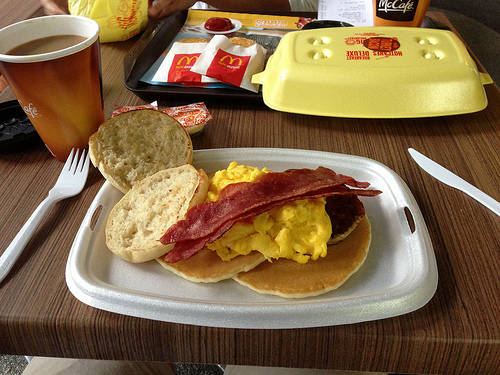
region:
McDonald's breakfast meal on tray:
[64, 108, 438, 327]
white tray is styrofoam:
[62, 148, 438, 329]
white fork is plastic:
[1, 148, 92, 279]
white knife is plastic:
[407, 146, 499, 217]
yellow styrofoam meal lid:
[250, 25, 494, 119]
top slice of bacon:
[157, 165, 371, 245]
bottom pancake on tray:
[230, 216, 371, 299]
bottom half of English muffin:
[103, 163, 210, 264]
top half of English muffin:
[87, 108, 194, 194]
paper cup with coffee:
[1, 14, 102, 162]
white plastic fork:
[2, 148, 90, 275]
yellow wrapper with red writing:
[66, 0, 147, 40]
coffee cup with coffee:
[1, 15, 107, 162]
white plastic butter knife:
[405, 145, 499, 216]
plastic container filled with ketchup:
[201, 15, 241, 36]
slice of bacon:
[159, 166, 371, 245]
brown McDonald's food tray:
[121, 8, 486, 108]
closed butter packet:
[161, 100, 216, 132]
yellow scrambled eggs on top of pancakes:
[201, 161, 326, 262]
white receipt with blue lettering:
[316, 0, 373, 28]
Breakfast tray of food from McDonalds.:
[61, 114, 438, 329]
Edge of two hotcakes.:
[191, 250, 358, 299]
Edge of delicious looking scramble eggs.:
[239, 210, 335, 266]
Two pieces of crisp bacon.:
[158, 167, 382, 225]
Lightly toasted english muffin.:
[88, 108, 201, 264]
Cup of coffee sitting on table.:
[5, 12, 105, 158]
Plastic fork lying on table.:
[1, 150, 98, 293]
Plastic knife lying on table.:
[407, 144, 499, 216]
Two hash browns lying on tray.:
[152, 32, 267, 100]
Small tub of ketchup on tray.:
[196, 15, 247, 40]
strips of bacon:
[148, 168, 390, 233]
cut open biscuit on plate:
[97, 116, 214, 254]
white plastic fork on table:
[4, 138, 98, 300]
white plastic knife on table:
[407, 138, 499, 229]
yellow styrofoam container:
[245, 31, 496, 116]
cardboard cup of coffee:
[2, 11, 109, 153]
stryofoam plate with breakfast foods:
[75, 114, 439, 331]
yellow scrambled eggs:
[209, 160, 330, 262]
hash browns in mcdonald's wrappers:
[147, 29, 272, 87]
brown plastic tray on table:
[115, 13, 486, 105]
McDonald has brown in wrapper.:
[205, 20, 264, 96]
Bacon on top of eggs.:
[172, 165, 359, 228]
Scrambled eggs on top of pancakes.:
[197, 164, 357, 299]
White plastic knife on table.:
[397, 135, 499, 220]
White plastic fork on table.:
[5, 144, 91, 302]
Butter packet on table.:
[162, 101, 215, 138]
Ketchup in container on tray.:
[198, 14, 243, 36]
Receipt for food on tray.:
[314, 0, 374, 30]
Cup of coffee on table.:
[2, 8, 114, 161]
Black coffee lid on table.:
[0, 89, 41, 165]